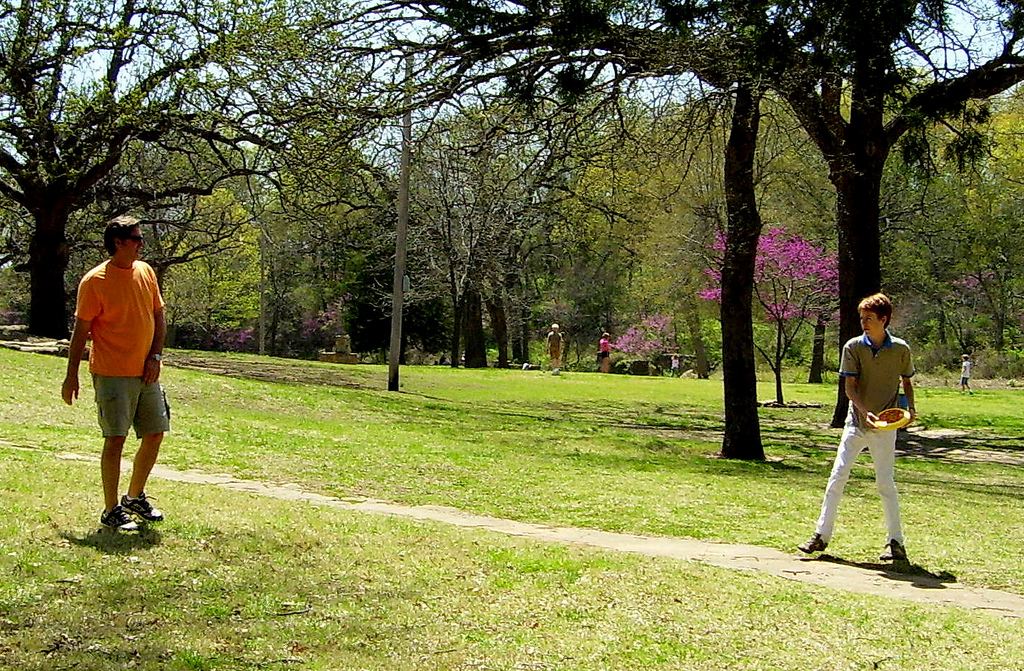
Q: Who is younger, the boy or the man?
A: The boy is younger than the man.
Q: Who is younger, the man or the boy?
A: The boy is younger than the man.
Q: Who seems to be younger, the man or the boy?
A: The boy is younger than the man.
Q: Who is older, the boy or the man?
A: The man is older than the boy.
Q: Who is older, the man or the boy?
A: The man is older than the boy.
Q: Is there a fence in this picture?
A: No, there are no fences.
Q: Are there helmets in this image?
A: No, there are no helmets.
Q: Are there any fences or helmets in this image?
A: No, there are no helmets or fences.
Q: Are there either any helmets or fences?
A: No, there are no helmets or fences.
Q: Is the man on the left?
A: Yes, the man is on the left of the image.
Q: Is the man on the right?
A: No, the man is on the left of the image.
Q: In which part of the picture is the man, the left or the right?
A: The man is on the left of the image.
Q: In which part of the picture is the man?
A: The man is on the left of the image.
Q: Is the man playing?
A: Yes, the man is playing.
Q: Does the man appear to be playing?
A: Yes, the man is playing.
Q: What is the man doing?
A: The man is playing.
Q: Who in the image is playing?
A: The man is playing.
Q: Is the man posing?
A: No, the man is playing.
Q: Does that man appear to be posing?
A: No, the man is playing.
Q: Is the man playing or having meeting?
A: The man is playing.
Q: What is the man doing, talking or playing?
A: The man is playing.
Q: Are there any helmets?
A: No, there are no helmets.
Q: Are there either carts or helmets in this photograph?
A: No, there are no helmets or carts.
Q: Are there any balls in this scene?
A: No, there are no balls.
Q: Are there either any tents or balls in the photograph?
A: No, there are no balls or tents.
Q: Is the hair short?
A: Yes, the hair is short.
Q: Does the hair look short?
A: Yes, the hair is short.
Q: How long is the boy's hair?
A: The hair is short.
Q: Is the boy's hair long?
A: No, the hair is short.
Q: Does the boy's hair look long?
A: No, the hair is short.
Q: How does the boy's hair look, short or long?
A: The hair is short.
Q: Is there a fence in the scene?
A: No, there are no fences.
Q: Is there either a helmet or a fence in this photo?
A: No, there are no fences or helmets.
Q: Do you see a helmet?
A: No, there are no helmets.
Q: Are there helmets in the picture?
A: No, there are no helmets.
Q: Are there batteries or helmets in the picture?
A: No, there are no helmets or batteries.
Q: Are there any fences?
A: No, there are no fences.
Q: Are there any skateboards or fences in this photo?
A: No, there are no fences or skateboards.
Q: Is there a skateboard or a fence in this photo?
A: No, there are no fences or skateboards.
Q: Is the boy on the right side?
A: Yes, the boy is on the right of the image.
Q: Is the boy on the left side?
A: No, the boy is on the right of the image.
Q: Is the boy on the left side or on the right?
A: The boy is on the right of the image.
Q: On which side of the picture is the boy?
A: The boy is on the right of the image.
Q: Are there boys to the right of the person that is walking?
A: Yes, there is a boy to the right of the person.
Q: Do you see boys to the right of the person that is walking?
A: Yes, there is a boy to the right of the person.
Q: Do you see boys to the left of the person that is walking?
A: No, the boy is to the right of the person.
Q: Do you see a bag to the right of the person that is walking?
A: No, there is a boy to the right of the person.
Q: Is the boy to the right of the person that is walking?
A: Yes, the boy is to the right of the person.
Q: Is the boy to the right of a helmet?
A: No, the boy is to the right of the person.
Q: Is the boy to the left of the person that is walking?
A: No, the boy is to the right of the person.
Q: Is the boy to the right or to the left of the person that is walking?
A: The boy is to the right of the person.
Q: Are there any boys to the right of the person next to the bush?
A: Yes, there is a boy to the right of the person.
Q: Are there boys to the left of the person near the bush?
A: No, the boy is to the right of the person.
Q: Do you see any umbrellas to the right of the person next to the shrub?
A: No, there is a boy to the right of the person.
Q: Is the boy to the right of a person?
A: Yes, the boy is to the right of a person.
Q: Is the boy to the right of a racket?
A: No, the boy is to the right of a person.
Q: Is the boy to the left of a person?
A: No, the boy is to the right of a person.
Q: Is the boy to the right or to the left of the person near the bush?
A: The boy is to the right of the person.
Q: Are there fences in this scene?
A: No, there are no fences.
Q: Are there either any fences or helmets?
A: No, there are no fences or helmets.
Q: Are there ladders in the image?
A: No, there are no ladders.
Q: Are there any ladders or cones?
A: No, there are no ladders or cones.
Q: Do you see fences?
A: No, there are no fences.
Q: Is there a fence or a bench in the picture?
A: No, there are no fences or benches.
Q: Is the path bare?
A: Yes, the path is bare.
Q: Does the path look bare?
A: Yes, the path is bare.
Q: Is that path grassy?
A: No, the path is bare.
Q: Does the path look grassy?
A: No, the path is bare.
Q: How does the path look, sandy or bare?
A: The path is bare.